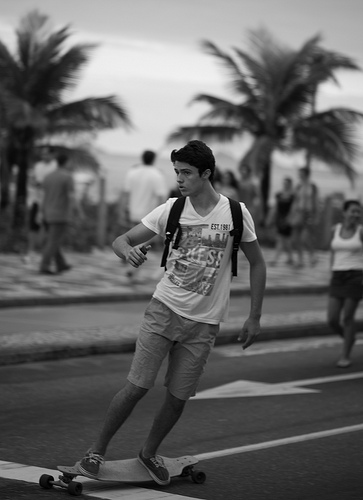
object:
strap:
[167, 203, 196, 241]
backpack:
[137, 192, 283, 256]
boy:
[67, 137, 275, 494]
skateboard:
[56, 461, 200, 482]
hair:
[168, 136, 224, 184]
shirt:
[141, 192, 257, 324]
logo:
[177, 246, 224, 265]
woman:
[321, 188, 359, 409]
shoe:
[66, 442, 198, 483]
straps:
[159, 194, 245, 278]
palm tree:
[166, 22, 362, 184]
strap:
[228, 197, 243, 254]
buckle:
[232, 244, 240, 251]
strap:
[220, 184, 254, 275]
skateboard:
[42, 450, 216, 482]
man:
[36, 153, 81, 277]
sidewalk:
[2, 244, 358, 297]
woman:
[325, 198, 362, 367]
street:
[0, 331, 361, 498]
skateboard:
[51, 424, 252, 490]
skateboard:
[83, 447, 191, 482]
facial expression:
[171, 159, 203, 200]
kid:
[74, 137, 268, 487]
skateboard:
[34, 452, 211, 498]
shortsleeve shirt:
[139, 194, 257, 327]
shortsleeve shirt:
[124, 165, 167, 222]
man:
[74, 142, 276, 485]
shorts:
[137, 296, 219, 401]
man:
[33, 147, 77, 274]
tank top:
[325, 222, 360, 274]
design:
[174, 224, 221, 304]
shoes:
[72, 443, 170, 485]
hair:
[165, 140, 215, 183]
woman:
[329, 200, 359, 378]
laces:
[86, 451, 103, 465]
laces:
[148, 453, 164, 469]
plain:
[2, 329, 359, 499]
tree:
[190, 24, 355, 240]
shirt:
[330, 222, 351, 271]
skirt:
[329, 267, 350, 300]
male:
[79, 139, 267, 486]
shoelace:
[82, 448, 105, 466]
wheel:
[191, 469, 207, 482]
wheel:
[65, 480, 84, 497]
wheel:
[41, 471, 54, 490]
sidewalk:
[0, 241, 331, 308]